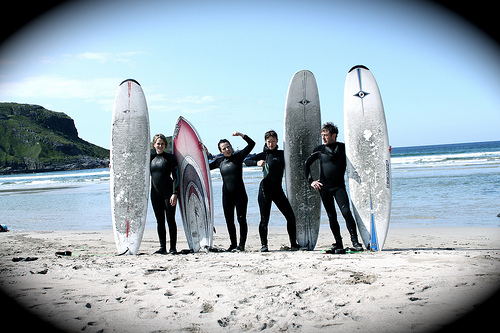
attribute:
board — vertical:
[278, 66, 325, 256]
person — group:
[304, 122, 361, 253]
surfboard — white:
[339, 70, 392, 184]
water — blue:
[2, 136, 498, 232]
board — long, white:
[284, 68, 323, 247]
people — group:
[149, 121, 369, 252]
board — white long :
[111, 77, 151, 256]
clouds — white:
[21, 78, 221, 125]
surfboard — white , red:
[171, 114, 217, 253]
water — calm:
[6, 132, 489, 240]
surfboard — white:
[319, 64, 436, 236]